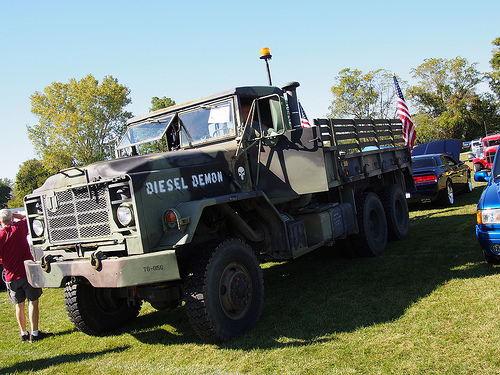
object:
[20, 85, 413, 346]
truck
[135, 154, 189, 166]
colors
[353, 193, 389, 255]
wheels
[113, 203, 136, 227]
lights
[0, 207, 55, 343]
man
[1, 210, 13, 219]
hat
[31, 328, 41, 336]
socks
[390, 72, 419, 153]
flag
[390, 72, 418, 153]
states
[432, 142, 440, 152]
black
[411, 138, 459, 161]
hood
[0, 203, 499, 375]
grass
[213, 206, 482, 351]
shadow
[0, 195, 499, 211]
ground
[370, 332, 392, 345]
spots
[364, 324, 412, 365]
cut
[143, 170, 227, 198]
words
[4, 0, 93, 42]
blue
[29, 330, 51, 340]
sneakers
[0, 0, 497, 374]
background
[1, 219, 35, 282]
shirt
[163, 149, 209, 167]
military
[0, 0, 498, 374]
daytime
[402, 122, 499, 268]
show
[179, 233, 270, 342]
wheel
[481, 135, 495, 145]
red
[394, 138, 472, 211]
diesel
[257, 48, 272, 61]
bubble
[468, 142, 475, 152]
white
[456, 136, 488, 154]
distance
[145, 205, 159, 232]
green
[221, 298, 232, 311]
gray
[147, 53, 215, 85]
clouds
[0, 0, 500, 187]
sky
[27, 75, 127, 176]
tree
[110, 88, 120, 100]
leaves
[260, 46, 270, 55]
orange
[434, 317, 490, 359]
light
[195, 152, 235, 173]
camo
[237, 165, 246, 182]
skull